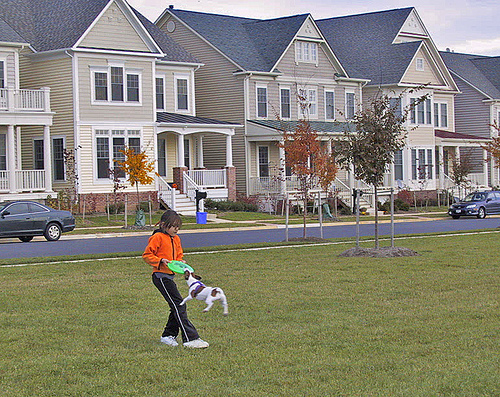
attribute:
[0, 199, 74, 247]
car — blue, dark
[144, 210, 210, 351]
girl — young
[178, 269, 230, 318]
dog — white, holding itself, brown, small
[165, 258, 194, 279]
frisbee — green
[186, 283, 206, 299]
patch — brown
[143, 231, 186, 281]
jacket — orange, fleece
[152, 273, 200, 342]
pants — white striped, blue, black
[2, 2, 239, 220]
house — two story, clean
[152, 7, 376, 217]
house — nice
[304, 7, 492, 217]
house — nice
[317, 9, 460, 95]
roof — blue colored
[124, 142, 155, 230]
tree — young, red, leafy, yellow leafed, short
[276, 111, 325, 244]
tree — leafy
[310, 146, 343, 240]
tree — red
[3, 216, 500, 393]
park — mowed, green, grassy, well trimmed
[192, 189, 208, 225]
mailbox — black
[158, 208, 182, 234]
hair — dark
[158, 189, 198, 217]
steps — white, in front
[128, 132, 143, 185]
window — large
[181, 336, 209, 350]
sport shoe — white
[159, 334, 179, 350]
sport shoe — white